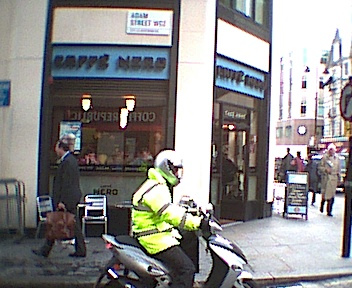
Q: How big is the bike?
A: The bike is small.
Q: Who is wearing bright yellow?
A: Man on the bike.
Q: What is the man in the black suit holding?
A: Bag.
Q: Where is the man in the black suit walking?
A: On the sidewalk.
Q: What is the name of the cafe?
A: Cafe Nero.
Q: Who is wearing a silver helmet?
A: The man on the scooter.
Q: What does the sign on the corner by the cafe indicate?
A: No right turns.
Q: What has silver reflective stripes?
A: The yellow jacket.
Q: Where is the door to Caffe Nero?
A: Catecorner to the street corner.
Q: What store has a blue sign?
A: Caffe Nero.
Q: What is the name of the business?
A: Cafe Nero.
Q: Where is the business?
A: On a corner.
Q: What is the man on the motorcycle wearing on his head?
A: A helmet.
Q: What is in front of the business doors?
A: A sign.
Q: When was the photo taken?
A: During the day.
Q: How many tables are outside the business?
A: One.